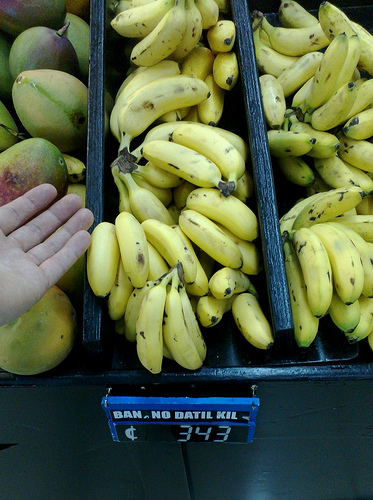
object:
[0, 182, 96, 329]
hand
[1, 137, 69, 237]
fruit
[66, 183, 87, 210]
fruit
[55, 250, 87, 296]
fruit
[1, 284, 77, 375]
fruit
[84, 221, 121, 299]
fruit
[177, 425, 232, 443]
price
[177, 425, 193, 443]
number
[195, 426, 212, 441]
number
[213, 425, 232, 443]
number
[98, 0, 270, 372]
bin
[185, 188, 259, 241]
banana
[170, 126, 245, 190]
banana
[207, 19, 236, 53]
banana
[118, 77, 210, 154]
banana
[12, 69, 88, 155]
fruit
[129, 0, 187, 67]
banana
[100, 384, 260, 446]
price sign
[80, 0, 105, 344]
seperator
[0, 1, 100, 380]
bin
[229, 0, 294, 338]
seperator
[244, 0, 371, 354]
bin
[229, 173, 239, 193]
stem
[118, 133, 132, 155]
stem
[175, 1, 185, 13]
stem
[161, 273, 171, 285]
stem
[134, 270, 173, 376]
banana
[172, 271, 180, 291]
stem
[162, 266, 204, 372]
banana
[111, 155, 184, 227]
bunch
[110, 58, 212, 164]
bunch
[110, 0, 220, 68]
bunch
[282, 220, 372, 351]
bunch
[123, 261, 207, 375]
bunch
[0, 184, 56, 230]
finger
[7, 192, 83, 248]
finger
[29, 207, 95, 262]
finger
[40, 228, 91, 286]
finger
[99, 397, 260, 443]
frame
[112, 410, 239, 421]
writing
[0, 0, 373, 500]
background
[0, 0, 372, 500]
fruit stand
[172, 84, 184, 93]
spot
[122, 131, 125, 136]
spot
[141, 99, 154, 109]
spot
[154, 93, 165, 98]
spot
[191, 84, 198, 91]
spot